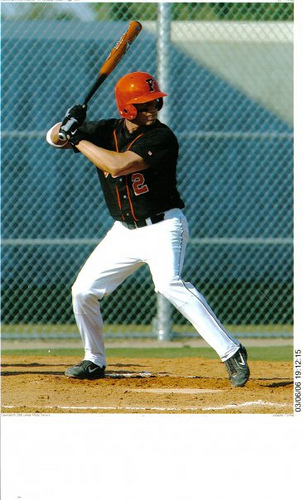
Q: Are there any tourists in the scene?
A: No, there are no tourists.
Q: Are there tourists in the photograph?
A: No, there are no tourists.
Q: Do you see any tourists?
A: No, there are no tourists.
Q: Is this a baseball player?
A: Yes, this is a baseball player.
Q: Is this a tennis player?
A: No, this is a baseball player.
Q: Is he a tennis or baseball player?
A: This is a baseball player.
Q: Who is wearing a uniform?
A: The player is wearing a uniform.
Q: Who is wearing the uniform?
A: The player is wearing a uniform.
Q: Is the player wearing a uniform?
A: Yes, the player is wearing a uniform.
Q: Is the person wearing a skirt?
A: No, the player is wearing a uniform.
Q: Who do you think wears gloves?
A: The player wears gloves.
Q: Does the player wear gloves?
A: Yes, the player wears gloves.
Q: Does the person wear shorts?
A: No, the player wears gloves.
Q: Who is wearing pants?
A: The player is wearing pants.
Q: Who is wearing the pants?
A: The player is wearing pants.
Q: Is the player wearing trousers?
A: Yes, the player is wearing trousers.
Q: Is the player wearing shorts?
A: No, the player is wearing trousers.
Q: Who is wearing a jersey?
A: The player is wearing a jersey.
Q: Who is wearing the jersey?
A: The player is wearing a jersey.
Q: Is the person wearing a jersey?
A: Yes, the player is wearing a jersey.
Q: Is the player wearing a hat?
A: No, the player is wearing a jersey.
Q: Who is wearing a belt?
A: The player is wearing a belt.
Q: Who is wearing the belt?
A: The player is wearing a belt.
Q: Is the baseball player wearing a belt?
A: Yes, the player is wearing a belt.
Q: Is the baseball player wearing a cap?
A: No, the player is wearing a belt.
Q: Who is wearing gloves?
A: The player is wearing gloves.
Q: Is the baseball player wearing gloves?
A: Yes, the player is wearing gloves.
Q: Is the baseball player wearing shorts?
A: No, the player is wearing gloves.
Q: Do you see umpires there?
A: No, there are no umpires.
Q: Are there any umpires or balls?
A: No, there are no umpires or balls.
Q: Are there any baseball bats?
A: Yes, there is a baseball bat.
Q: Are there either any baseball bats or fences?
A: Yes, there is a baseball bat.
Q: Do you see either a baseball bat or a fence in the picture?
A: Yes, there is a baseball bat.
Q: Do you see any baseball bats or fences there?
A: Yes, there is a baseball bat.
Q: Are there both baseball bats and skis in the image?
A: No, there is a baseball bat but no skis.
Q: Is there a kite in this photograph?
A: No, there are no kites.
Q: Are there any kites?
A: No, there are no kites.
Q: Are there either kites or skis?
A: No, there are no kites or skis.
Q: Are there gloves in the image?
A: Yes, there are gloves.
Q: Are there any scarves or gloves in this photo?
A: Yes, there are gloves.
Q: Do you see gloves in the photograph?
A: Yes, there are gloves.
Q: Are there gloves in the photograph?
A: Yes, there are gloves.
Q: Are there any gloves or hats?
A: Yes, there are gloves.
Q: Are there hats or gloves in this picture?
A: Yes, there are gloves.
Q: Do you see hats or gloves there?
A: Yes, there are gloves.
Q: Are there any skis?
A: No, there are no skis.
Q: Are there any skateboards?
A: No, there are no skateboards.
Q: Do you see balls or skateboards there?
A: No, there are no skateboards or balls.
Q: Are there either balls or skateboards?
A: No, there are no skateboards or balls.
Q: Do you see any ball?
A: No, there are no balls.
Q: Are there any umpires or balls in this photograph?
A: No, there are no balls or umpires.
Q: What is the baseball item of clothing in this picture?
A: The clothing item is a uniform.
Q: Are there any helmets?
A: Yes, there is a helmet.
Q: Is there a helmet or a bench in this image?
A: Yes, there is a helmet.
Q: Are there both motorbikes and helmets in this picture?
A: No, there is a helmet but no motorcycles.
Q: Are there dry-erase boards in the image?
A: No, there are no dry-erase boards.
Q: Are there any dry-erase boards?
A: No, there are no dry-erase boards.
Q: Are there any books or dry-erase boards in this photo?
A: No, there are no dry-erase boards or books.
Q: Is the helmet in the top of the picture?
A: Yes, the helmet is in the top of the image.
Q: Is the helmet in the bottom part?
A: No, the helmet is in the top of the image.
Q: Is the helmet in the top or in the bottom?
A: The helmet is in the top of the image.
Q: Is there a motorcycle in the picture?
A: No, there are no motorcycles.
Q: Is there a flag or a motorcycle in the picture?
A: No, there are no motorcycles or flags.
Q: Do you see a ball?
A: No, there are no balls.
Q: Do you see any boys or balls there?
A: No, there are no balls or boys.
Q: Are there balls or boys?
A: No, there are no balls or boys.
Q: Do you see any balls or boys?
A: No, there are no balls or boys.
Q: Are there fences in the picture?
A: Yes, there is a fence.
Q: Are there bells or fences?
A: Yes, there is a fence.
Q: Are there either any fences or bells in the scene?
A: Yes, there is a fence.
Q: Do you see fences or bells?
A: Yes, there is a fence.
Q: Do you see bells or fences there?
A: Yes, there is a fence.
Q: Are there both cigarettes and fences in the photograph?
A: No, there is a fence but no cigarettes.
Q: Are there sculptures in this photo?
A: No, there are no sculptures.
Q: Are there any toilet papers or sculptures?
A: No, there are no sculptures or toilet papers.